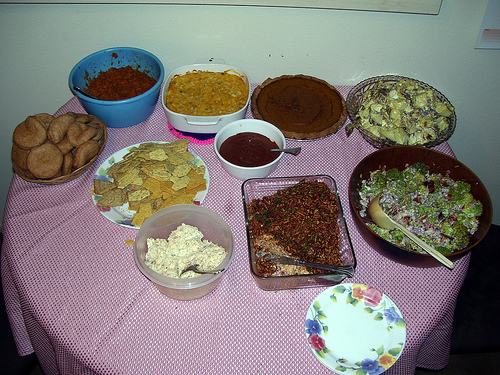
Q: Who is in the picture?
A: No one.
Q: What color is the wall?
A: White.